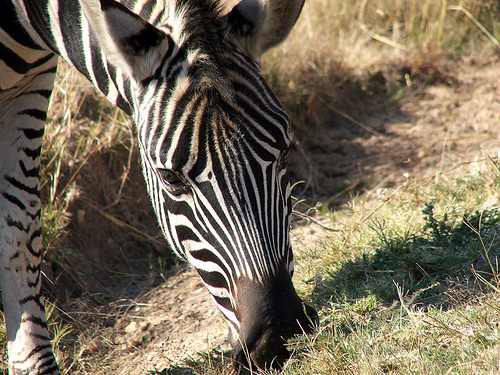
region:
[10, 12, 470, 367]
The zebra is out in a field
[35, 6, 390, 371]
The zebra is eating some grass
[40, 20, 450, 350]
The zebra is watching for danger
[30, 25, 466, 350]
The zebra is getting some food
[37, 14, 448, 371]
A zebra is looking for food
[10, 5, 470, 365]
A zebra is out in the daytime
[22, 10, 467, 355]
The zebra is enjoying the sunshine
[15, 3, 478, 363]
The zebra is listening very carefully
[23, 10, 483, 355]
The zebra is casting a shadow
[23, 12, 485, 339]
The zebra is enjoying the day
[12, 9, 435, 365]
the head of a giraffe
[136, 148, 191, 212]
an eye of a giraffe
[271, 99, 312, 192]
an eye of a giraffe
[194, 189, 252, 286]
the stripes on a giraffe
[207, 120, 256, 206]
the stripes on a giraffe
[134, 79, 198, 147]
the stripes on a giraffe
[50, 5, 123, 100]
the stripes on a giraffe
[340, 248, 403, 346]
this is a patch of grass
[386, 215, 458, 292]
this is a patch of grass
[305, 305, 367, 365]
this is a patch of grass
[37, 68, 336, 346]
zebra standing in the grass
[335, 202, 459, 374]
grass on the ground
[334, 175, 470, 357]
the grass is green and brown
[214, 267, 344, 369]
the zebras has a black nose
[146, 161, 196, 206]
zebra has black eye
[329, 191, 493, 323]
shadow from the zebra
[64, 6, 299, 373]
zebra has black and white stripes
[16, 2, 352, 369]
zebra is eating grass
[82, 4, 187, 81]
zebra has black and white ears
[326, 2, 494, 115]
tall grass behind the zebra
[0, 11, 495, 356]
The zebra is standing in the grass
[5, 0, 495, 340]
A zebra is eating the grass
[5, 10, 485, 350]
A zebra is watching for danger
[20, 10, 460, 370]
A zebra is a full grown female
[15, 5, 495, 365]
A zebra is listening very closely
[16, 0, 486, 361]
A zebra is alert for predators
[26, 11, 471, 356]
A zebra is casting a shadow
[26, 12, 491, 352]
A zebra is out in the sunshine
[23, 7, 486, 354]
A zebra is enjoying the day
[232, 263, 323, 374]
the zebra has a black snout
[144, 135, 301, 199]
the black eyes are open on the zebra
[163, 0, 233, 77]
the zebra's mane is black and white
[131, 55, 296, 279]
the zebra's head is black and white stripes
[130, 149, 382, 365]
the zebra's nose is in the grass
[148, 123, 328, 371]
the zebra is grazing on grass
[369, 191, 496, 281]
weeds are in the grass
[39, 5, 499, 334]
a dirt pathway is behind the zebra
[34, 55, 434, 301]
a dirt bank is behind the animal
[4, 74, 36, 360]
the inner leg of the zebra is white